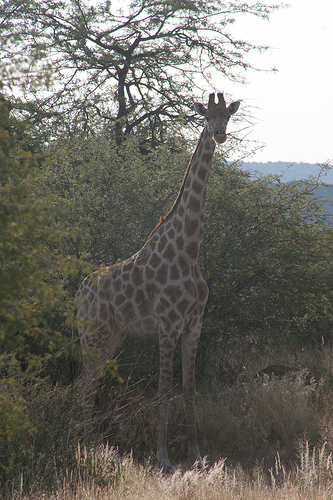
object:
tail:
[68, 303, 80, 408]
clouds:
[1, 0, 333, 164]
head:
[192, 90, 243, 144]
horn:
[216, 89, 226, 107]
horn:
[207, 91, 217, 107]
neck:
[156, 130, 216, 246]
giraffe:
[66, 88, 245, 478]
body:
[68, 225, 215, 474]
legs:
[158, 305, 181, 462]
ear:
[193, 100, 212, 118]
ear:
[228, 94, 244, 121]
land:
[0, 334, 333, 497]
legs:
[76, 301, 107, 453]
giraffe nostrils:
[213, 129, 223, 143]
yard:
[0, 338, 333, 499]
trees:
[0, 0, 285, 242]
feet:
[155, 449, 174, 474]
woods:
[115, 96, 127, 143]